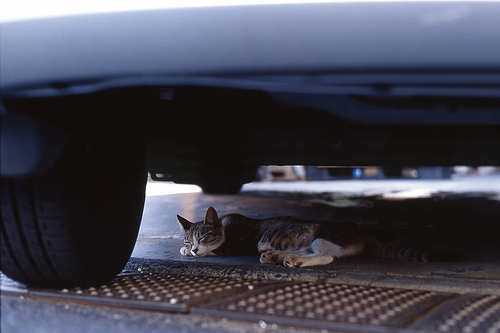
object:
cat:
[177, 206, 466, 269]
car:
[2, 0, 500, 292]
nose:
[192, 246, 198, 254]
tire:
[1, 95, 147, 289]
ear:
[204, 206, 219, 225]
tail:
[366, 239, 467, 264]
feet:
[283, 254, 301, 268]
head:
[175, 207, 222, 255]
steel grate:
[2, 266, 500, 332]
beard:
[199, 235, 226, 253]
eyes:
[184, 238, 193, 245]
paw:
[180, 246, 191, 257]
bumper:
[1, 1, 499, 97]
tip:
[442, 252, 466, 264]